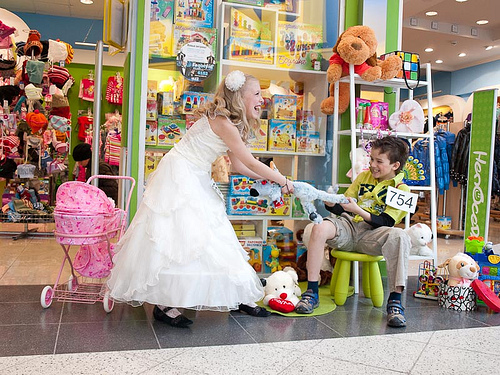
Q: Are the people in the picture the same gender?
A: No, they are both male and female.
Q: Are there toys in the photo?
A: Yes, there is a toy.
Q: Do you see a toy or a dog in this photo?
A: Yes, there is a toy.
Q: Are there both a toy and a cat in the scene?
A: No, there is a toy but no cats.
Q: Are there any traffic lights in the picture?
A: No, there are no traffic lights.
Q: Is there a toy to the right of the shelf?
A: Yes, there is a toy to the right of the shelf.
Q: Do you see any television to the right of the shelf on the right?
A: No, there is a toy to the right of the shelf.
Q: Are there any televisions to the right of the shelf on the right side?
A: No, there is a toy to the right of the shelf.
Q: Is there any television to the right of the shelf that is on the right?
A: No, there is a toy to the right of the shelf.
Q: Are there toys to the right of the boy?
A: Yes, there is a toy to the right of the boy.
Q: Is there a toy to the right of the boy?
A: Yes, there is a toy to the right of the boy.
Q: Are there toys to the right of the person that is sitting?
A: Yes, there is a toy to the right of the boy.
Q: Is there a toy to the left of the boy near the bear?
A: No, the toy is to the right of the boy.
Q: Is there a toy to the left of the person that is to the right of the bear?
A: No, the toy is to the right of the boy.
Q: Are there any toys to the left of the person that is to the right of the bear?
A: No, the toy is to the right of the boy.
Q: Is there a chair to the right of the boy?
A: No, there is a toy to the right of the boy.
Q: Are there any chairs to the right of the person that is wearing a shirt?
A: No, there is a toy to the right of the boy.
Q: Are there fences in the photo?
A: No, there are no fences.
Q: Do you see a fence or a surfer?
A: No, there are no fences or surfers.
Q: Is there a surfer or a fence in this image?
A: No, there are no fences or surfers.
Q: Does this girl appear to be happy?
A: Yes, the girl is happy.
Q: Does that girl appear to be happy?
A: Yes, the girl is happy.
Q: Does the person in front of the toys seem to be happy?
A: Yes, the girl is happy.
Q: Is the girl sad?
A: No, the girl is happy.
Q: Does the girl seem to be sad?
A: No, the girl is happy.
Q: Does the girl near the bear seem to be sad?
A: No, the girl is happy.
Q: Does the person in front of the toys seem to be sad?
A: No, the girl is happy.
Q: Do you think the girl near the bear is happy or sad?
A: The girl is happy.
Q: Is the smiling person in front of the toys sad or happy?
A: The girl is happy.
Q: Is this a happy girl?
A: Yes, this is a happy girl.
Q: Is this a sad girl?
A: No, this is a happy girl.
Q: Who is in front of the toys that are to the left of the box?
A: The girl is in front of the toys.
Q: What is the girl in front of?
A: The girl is in front of the toys.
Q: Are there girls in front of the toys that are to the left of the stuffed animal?
A: Yes, there is a girl in front of the toys.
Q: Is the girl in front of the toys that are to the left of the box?
A: Yes, the girl is in front of the toys.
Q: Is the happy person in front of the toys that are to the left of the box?
A: Yes, the girl is in front of the toys.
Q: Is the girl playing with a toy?
A: Yes, the girl is playing with a toy.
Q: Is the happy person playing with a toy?
A: Yes, the girl is playing with a toy.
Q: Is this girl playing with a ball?
A: No, the girl is playing with a toy.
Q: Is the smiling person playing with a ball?
A: No, the girl is playing with a toy.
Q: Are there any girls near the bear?
A: Yes, there is a girl near the bear.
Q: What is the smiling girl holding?
A: The girl is holding the toy.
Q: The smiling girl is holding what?
A: The girl is holding the toy.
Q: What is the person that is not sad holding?
A: The girl is holding the toy.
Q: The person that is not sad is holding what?
A: The girl is holding the toy.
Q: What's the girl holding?
A: The girl is holding the toy.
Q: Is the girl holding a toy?
A: Yes, the girl is holding a toy.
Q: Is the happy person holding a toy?
A: Yes, the girl is holding a toy.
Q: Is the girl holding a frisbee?
A: No, the girl is holding a toy.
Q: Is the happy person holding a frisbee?
A: No, the girl is holding a toy.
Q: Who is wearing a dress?
A: The girl is wearing a dress.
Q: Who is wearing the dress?
A: The girl is wearing a dress.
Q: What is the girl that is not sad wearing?
A: The girl is wearing a dress.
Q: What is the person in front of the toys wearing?
A: The girl is wearing a dress.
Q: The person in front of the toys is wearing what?
A: The girl is wearing a dress.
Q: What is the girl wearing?
A: The girl is wearing a dress.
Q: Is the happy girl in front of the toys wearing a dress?
A: Yes, the girl is wearing a dress.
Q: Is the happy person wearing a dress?
A: Yes, the girl is wearing a dress.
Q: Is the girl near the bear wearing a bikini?
A: No, the girl is wearing a dress.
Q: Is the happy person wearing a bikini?
A: No, the girl is wearing a dress.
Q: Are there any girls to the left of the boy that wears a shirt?
A: Yes, there is a girl to the left of the boy.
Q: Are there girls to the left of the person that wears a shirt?
A: Yes, there is a girl to the left of the boy.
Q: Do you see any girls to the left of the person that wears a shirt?
A: Yes, there is a girl to the left of the boy.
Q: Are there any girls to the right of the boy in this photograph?
A: No, the girl is to the left of the boy.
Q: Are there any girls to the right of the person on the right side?
A: No, the girl is to the left of the boy.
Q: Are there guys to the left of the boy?
A: No, there is a girl to the left of the boy.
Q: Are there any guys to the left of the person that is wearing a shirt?
A: No, there is a girl to the left of the boy.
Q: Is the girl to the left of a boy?
A: Yes, the girl is to the left of a boy.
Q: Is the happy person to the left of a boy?
A: Yes, the girl is to the left of a boy.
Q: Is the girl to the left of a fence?
A: No, the girl is to the left of a boy.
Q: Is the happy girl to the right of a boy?
A: No, the girl is to the left of a boy.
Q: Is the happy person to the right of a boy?
A: No, the girl is to the left of a boy.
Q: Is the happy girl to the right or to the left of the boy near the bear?
A: The girl is to the left of the boy.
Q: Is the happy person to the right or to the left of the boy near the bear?
A: The girl is to the left of the boy.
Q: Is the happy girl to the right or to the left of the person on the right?
A: The girl is to the left of the boy.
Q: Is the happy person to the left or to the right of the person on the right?
A: The girl is to the left of the boy.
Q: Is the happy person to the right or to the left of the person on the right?
A: The girl is to the left of the boy.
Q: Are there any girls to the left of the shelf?
A: Yes, there is a girl to the left of the shelf.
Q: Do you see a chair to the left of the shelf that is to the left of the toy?
A: No, there is a girl to the left of the shelf.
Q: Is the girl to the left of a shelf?
A: Yes, the girl is to the left of a shelf.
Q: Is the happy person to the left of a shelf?
A: Yes, the girl is to the left of a shelf.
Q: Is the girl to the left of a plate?
A: No, the girl is to the left of a shelf.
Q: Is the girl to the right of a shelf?
A: No, the girl is to the left of a shelf.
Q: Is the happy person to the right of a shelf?
A: No, the girl is to the left of a shelf.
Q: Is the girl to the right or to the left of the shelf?
A: The girl is to the left of the shelf.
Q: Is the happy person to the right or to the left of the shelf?
A: The girl is to the left of the shelf.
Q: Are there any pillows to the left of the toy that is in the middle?
A: No, there is a girl to the left of the toy.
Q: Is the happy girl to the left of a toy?
A: Yes, the girl is to the left of a toy.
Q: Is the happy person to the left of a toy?
A: Yes, the girl is to the left of a toy.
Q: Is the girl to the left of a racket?
A: No, the girl is to the left of a toy.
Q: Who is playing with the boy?
A: The girl is playing with the boy.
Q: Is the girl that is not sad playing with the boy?
A: Yes, the girl is playing with the boy.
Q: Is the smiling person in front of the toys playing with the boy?
A: Yes, the girl is playing with the boy.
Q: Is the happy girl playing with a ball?
A: No, the girl is playing with the boy.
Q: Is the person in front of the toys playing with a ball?
A: No, the girl is playing with the boy.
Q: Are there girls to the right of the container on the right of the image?
A: No, the girl is to the left of the box.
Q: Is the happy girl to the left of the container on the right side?
A: Yes, the girl is to the left of the box.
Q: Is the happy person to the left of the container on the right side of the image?
A: Yes, the girl is to the left of the box.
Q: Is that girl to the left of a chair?
A: No, the girl is to the left of the box.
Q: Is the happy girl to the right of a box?
A: No, the girl is to the left of a box.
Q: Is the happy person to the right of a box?
A: No, the girl is to the left of a box.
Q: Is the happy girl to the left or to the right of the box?
A: The girl is to the left of the box.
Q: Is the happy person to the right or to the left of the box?
A: The girl is to the left of the box.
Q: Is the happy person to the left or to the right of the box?
A: The girl is to the left of the box.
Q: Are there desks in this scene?
A: No, there are no desks.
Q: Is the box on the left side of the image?
A: No, the box is on the right of the image.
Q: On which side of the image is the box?
A: The box is on the right of the image.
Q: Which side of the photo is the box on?
A: The box is on the right of the image.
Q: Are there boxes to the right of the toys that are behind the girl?
A: Yes, there is a box to the right of the toys.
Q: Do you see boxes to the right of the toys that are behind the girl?
A: Yes, there is a box to the right of the toys.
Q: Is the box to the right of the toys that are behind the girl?
A: Yes, the box is to the right of the toys.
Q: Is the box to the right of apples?
A: No, the box is to the right of the toys.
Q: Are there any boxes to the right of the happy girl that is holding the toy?
A: Yes, there is a box to the right of the girl.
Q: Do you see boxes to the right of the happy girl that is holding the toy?
A: Yes, there is a box to the right of the girl.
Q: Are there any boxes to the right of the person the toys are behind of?
A: Yes, there is a box to the right of the girl.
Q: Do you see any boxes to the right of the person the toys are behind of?
A: Yes, there is a box to the right of the girl.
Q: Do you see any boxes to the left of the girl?
A: No, the box is to the right of the girl.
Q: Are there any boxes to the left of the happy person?
A: No, the box is to the right of the girl.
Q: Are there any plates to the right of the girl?
A: No, there is a box to the right of the girl.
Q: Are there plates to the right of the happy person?
A: No, there is a box to the right of the girl.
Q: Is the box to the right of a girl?
A: Yes, the box is to the right of a girl.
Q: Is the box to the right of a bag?
A: No, the box is to the right of a girl.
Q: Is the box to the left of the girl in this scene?
A: No, the box is to the right of the girl.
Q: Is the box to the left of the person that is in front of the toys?
A: No, the box is to the right of the girl.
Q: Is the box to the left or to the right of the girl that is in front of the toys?
A: The box is to the right of the girl.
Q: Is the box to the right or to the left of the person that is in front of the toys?
A: The box is to the right of the girl.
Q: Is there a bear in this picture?
A: Yes, there is a bear.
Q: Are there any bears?
A: Yes, there is a bear.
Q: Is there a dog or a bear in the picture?
A: Yes, there is a bear.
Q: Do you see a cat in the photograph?
A: No, there are no cats.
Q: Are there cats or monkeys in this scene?
A: No, there are no cats or monkeys.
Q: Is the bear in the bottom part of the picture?
A: Yes, the bear is in the bottom of the image.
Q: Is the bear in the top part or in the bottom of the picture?
A: The bear is in the bottom of the image.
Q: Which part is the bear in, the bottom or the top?
A: The bear is in the bottom of the image.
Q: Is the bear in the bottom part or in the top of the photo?
A: The bear is in the bottom of the image.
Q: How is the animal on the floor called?
A: The animal is a bear.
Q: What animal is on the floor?
A: The animal is a bear.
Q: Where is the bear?
A: The bear is on the floor.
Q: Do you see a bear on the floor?
A: Yes, there is a bear on the floor.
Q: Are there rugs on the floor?
A: No, there is a bear on the floor.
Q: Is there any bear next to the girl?
A: Yes, there is a bear next to the girl.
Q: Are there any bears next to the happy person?
A: Yes, there is a bear next to the girl.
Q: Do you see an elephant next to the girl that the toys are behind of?
A: No, there is a bear next to the girl.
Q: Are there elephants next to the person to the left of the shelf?
A: No, there is a bear next to the girl.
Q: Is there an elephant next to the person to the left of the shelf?
A: No, there is a bear next to the girl.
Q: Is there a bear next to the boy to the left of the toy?
A: Yes, there is a bear next to the boy.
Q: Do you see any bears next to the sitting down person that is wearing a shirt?
A: Yes, there is a bear next to the boy.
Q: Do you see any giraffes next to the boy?
A: No, there is a bear next to the boy.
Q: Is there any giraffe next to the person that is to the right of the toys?
A: No, there is a bear next to the boy.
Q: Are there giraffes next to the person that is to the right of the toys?
A: No, there is a bear next to the boy.